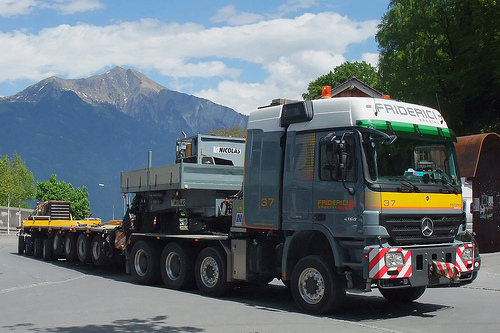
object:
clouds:
[0, 11, 370, 62]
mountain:
[0, 62, 248, 220]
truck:
[11, 99, 480, 310]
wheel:
[89, 237, 110, 268]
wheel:
[155, 242, 191, 288]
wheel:
[192, 245, 227, 298]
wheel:
[289, 253, 345, 315]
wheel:
[49, 233, 64, 259]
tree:
[376, 0, 495, 139]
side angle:
[240, 97, 372, 311]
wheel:
[129, 240, 159, 286]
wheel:
[75, 233, 92, 264]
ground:
[0, 232, 500, 333]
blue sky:
[0, 0, 388, 109]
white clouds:
[0, 10, 387, 81]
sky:
[0, 0, 394, 116]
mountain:
[3, 62, 253, 219]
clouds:
[0, 0, 383, 116]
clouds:
[162, 57, 242, 82]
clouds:
[233, 9, 375, 61]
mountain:
[0, 62, 247, 215]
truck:
[16, 98, 485, 308]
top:
[248, 97, 451, 134]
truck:
[18, 95, 485, 313]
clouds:
[0, 12, 380, 89]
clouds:
[226, 27, 310, 82]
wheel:
[285, 255, 345, 314]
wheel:
[63, 233, 77, 263]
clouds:
[123, 10, 386, 70]